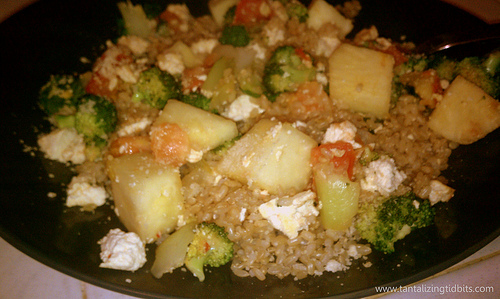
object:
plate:
[1, 1, 500, 299]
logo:
[373, 283, 497, 294]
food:
[25, 1, 500, 282]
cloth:
[1, 236, 498, 299]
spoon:
[350, 0, 500, 57]